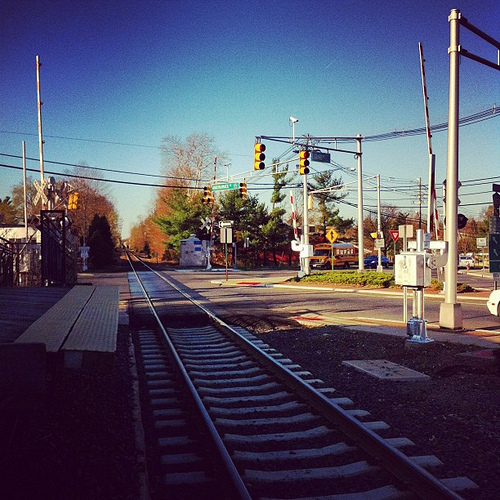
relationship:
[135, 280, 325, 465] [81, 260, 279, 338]
tracks crossing road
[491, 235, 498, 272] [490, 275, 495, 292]
street sign on pole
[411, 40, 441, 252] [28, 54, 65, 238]
gate with gate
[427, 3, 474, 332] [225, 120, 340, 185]
pole with traffic lights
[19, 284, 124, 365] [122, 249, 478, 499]
bench next to tracks